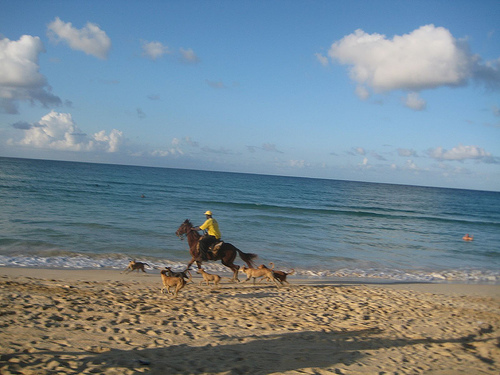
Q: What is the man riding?
A: A horse.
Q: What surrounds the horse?
A: Dogs.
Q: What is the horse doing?
A: Running.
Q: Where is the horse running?
A: On the beach.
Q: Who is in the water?
A: A man.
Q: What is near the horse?
A: Dogs.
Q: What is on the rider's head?
A: A white helmet.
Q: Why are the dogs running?
A: They're chasing the horse.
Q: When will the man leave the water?
A: When he is done swimming.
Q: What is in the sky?
A: Clouds.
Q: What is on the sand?
A: Footprints.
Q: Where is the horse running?
A: On the beach.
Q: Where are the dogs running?
A: On the beach.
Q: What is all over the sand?
A: Footprints.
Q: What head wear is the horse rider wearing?
A: Hat.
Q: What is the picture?
A: Ocean.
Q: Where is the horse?
A: The beach.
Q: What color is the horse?
A: Brown.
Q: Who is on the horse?
A: A guy.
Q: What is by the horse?
A: Dogs.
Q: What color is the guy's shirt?
A: Yellow.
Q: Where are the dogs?
A: Around the horse.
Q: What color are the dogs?
A: Brown.